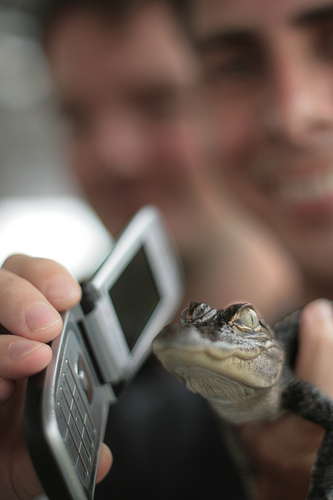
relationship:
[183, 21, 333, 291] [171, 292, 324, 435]
man holding snake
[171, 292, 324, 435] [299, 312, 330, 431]
snake in hand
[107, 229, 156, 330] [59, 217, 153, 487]
screen of cellphone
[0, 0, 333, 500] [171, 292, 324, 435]
man behind snake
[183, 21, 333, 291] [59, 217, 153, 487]
man holding cellphone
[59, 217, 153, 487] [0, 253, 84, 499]
cellphone in hand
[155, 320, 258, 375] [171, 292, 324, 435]
mouth of snake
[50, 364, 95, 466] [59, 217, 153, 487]
controls of cellphone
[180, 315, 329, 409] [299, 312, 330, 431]
alligator in hand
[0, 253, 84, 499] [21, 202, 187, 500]
hand holding cellphone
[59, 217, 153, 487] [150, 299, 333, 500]
cellphone next to lizard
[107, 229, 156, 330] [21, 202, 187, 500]
screen of cellphone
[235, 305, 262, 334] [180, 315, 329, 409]
eye of alligator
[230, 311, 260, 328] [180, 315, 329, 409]
eye of alligator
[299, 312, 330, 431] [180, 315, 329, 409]
hand holding alligator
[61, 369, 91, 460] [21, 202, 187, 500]
buttons on cellphone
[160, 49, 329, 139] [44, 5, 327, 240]
faces of men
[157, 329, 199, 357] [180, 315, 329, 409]
snout of alligator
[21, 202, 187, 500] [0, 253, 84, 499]
cellphone in hand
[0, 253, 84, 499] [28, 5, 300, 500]
hand of men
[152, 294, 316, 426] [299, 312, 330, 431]
dinosaur in hand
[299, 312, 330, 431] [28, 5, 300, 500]
hand of men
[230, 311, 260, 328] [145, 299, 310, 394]
eye of lizard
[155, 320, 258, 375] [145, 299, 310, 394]
mouth of lizard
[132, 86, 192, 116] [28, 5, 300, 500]
eye of men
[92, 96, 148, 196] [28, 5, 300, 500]
nose of men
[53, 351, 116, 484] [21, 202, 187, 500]
keypad on cellphone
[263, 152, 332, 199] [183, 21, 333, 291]
smile on man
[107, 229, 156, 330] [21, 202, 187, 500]
screen on cellphone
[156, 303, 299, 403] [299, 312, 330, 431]
frog in hand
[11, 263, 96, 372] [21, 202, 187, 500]
fingers on cellphone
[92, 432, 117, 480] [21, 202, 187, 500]
thumb supporting cellphone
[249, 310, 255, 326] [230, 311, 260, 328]
slit on eye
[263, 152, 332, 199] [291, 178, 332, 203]
smile exposing teeth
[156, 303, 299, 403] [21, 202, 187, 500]
frog next to cellphone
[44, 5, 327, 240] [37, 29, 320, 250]
men in background